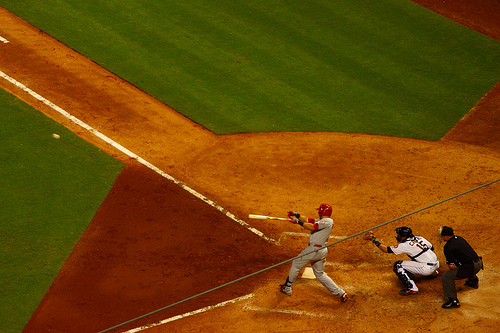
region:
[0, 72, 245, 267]
white line drawn on baseball field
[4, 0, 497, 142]
green grass on baseball field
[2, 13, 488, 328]
dirt ground on baseball field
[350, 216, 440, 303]
catcher behind batter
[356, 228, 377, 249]
brown catcher's mitt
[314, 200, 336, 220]
red helmet on baseball batter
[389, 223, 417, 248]
black catcher's helmet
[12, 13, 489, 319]
A large baseball field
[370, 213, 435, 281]
The catcher behind the batter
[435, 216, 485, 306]
The umpire behind the catcher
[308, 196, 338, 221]
Batter wearing a red helmet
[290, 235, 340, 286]
A grey uniform with red trim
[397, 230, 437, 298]
White uniform with black trim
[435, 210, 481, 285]
A black umpire uniform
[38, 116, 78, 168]
Baseball flying through the air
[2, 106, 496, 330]
a baseball game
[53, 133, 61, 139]
the ball of baseball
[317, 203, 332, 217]
the red helmet of player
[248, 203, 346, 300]
the baseball player hitting the ball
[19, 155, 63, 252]
many grass in the field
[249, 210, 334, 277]
the swing of the bat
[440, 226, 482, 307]
he is dress in black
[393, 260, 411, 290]
the leg protector is black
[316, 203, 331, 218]
the head of the player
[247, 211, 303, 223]
A wooden baseball bat about to be tossed.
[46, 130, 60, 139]
A baseball flying through the air after being hit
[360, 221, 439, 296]
A catcher who is still trying to catch the ball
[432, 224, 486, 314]
An umpire wearing black and squatting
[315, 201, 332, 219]
A red baseball helmet on the batter.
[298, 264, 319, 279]
Home plate which is behind the batter.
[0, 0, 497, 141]
The grass outside of the infield.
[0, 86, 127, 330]
The infield grass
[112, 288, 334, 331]
Chalk that defines the line from 3rd base to home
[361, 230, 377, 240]
A catcher's mitt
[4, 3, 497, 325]
A baseball field.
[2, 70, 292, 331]
White stripes on a ball field.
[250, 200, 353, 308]
A baseball player.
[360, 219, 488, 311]
A catcher and an umpire.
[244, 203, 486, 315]
Three people playing a ball game.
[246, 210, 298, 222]
A baseball bat.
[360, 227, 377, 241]
A brown catcher's mitt.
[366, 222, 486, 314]
An umpire behind a catcher.